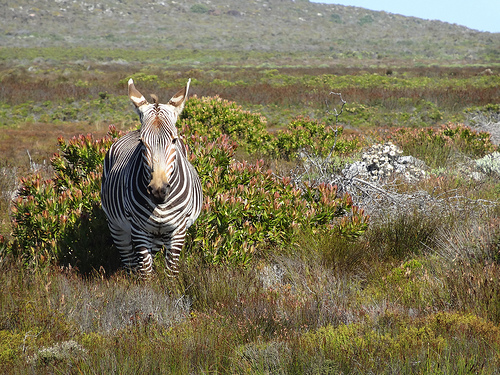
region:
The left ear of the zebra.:
[125, 72, 151, 117]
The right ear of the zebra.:
[170, 81, 194, 108]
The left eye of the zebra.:
[136, 135, 146, 145]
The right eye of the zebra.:
[166, 135, 176, 143]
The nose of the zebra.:
[146, 182, 172, 194]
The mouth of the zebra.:
[148, 193, 167, 201]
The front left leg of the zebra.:
[135, 225, 154, 278]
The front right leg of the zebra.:
[161, 233, 185, 283]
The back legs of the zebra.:
[115, 240, 160, 281]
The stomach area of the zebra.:
[105, 135, 202, 231]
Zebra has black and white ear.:
[167, 80, 207, 114]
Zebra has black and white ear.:
[115, 73, 157, 110]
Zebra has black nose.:
[148, 183, 175, 196]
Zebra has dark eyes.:
[126, 116, 197, 150]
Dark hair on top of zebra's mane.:
[149, 88, 169, 113]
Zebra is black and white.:
[91, 173, 227, 235]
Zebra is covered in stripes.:
[107, 135, 194, 222]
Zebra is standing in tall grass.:
[101, 202, 231, 324]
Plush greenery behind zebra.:
[218, 161, 285, 245]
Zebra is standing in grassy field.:
[26, 57, 439, 334]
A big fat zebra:
[104, 84, 204, 276]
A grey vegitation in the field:
[65, 285, 180, 319]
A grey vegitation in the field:
[30, 330, 95, 370]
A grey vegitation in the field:
[318, 144, 418, 216]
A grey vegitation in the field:
[397, 200, 492, 251]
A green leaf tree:
[200, 164, 272, 246]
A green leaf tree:
[261, 155, 381, 252]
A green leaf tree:
[8, 167, 88, 251]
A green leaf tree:
[192, 93, 263, 147]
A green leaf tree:
[405, 107, 486, 155]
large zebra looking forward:
[75, 28, 224, 289]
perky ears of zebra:
[111, 73, 197, 113]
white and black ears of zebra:
[125, 71, 199, 121]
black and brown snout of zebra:
[147, 170, 169, 197]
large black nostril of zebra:
[143, 183, 157, 196]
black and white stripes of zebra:
[172, 165, 200, 215]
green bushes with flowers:
[216, 165, 297, 255]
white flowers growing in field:
[341, 112, 425, 224]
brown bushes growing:
[242, 78, 364, 103]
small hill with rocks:
[264, 14, 434, 54]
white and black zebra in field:
[90, 59, 232, 299]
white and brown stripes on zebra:
[114, 182, 173, 237]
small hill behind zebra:
[3, 3, 468, 120]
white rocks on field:
[355, 122, 438, 191]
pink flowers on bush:
[221, 140, 256, 202]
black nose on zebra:
[130, 162, 203, 207]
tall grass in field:
[146, 330, 298, 362]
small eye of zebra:
[164, 132, 193, 152]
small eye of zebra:
[122, 133, 152, 150]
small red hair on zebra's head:
[146, 110, 173, 138]